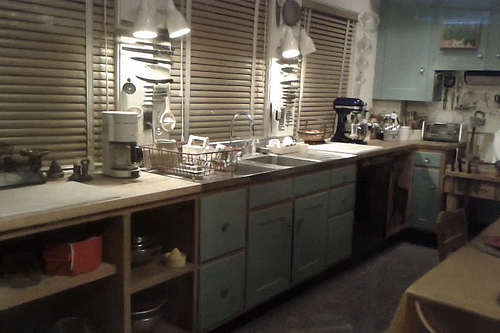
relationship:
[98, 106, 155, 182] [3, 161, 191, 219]
coffee maker on counter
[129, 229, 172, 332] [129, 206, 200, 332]
bowls are on shelf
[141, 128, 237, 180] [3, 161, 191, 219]
dish rack on counter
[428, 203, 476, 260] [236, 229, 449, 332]
chair on ground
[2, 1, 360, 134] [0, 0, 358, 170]
blinds are in blinds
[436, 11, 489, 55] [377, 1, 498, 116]
painting on cupboard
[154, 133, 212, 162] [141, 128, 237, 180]
dishes are in dish rack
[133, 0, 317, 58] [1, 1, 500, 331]
light are in kitchen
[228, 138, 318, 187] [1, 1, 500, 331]
sink in kitchen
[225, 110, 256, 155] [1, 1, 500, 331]
faucet in kitchen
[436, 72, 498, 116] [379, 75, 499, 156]
utensils are on wall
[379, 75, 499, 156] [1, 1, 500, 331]
wall in kitchen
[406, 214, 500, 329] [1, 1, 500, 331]
table in kitchen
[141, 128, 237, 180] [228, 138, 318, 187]
dish rack by sink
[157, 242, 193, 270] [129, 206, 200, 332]
fruit juicer on shelf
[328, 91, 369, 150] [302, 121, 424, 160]
mixer on counter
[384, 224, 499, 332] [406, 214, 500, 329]
tablecloth on table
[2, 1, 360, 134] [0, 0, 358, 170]
blinds are over blinds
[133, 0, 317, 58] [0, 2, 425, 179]
light are on wall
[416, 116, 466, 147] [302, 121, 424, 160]
toaster oven on counter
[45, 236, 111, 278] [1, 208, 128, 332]
pot on shelf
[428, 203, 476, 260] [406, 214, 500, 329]
chair by table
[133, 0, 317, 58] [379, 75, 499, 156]
light are on wall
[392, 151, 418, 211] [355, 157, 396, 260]
towel by oven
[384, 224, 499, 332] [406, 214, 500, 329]
tablecloth over table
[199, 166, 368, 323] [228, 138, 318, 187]
cabinets are under sink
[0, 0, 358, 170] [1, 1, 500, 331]
blinds in kitchen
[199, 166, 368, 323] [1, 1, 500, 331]
cabinets are in kitchen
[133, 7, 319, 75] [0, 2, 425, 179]
light on wall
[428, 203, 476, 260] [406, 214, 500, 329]
chair at table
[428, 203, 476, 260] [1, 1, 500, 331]
chair in kitchen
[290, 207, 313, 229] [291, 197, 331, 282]
handle on cabinet door